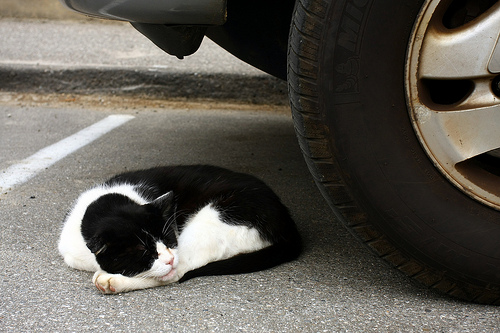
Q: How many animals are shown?
A: One.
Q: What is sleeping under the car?
A: A cat.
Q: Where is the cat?
A: Under the car.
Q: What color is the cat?
A: Black and white.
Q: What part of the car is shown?
A: The wheel.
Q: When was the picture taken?
A: Daytime.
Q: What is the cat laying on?
A: The road.